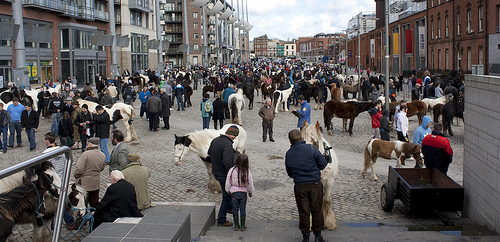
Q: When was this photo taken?
A: Daytime.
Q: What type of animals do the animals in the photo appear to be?
A: Miniature horses.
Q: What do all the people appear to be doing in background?
A: Walking towards horses.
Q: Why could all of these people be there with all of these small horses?
A: Miniature horse convention.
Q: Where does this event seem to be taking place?
A: On city street.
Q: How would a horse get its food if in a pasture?
A: By grazing.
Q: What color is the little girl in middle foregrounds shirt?
A: Pink.